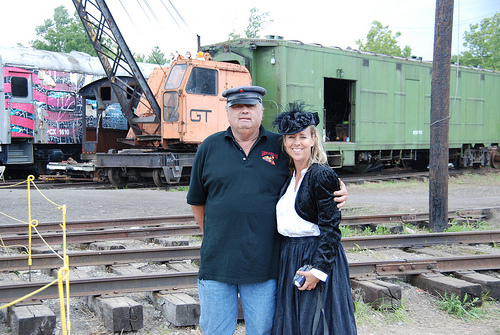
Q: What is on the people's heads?
A: Hats.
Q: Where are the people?
A: Train yard.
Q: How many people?
A: Two.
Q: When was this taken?
A: During the day.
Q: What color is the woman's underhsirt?
A: White.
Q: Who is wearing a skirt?
A: The woman.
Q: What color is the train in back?
A: Green.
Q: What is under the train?
A: Tracks.